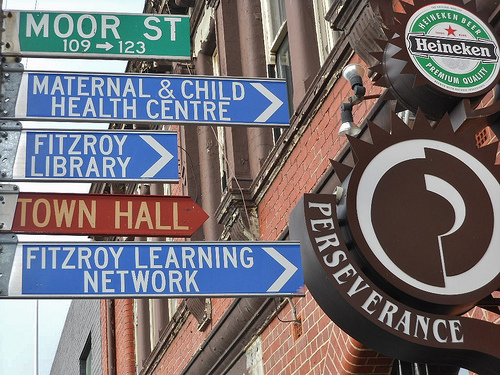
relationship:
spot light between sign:
[327, 59, 379, 134] [292, 106, 496, 356]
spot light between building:
[327, 59, 379, 134] [46, 1, 495, 373]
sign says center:
[0, 69, 292, 128] [29, 28, 424, 330]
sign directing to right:
[0, 69, 292, 128] [206, 17, 468, 368]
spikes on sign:
[303, 106, 499, 167] [303, 106, 498, 370]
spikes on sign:
[368, 0, 426, 94] [367, 1, 499, 105]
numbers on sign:
[61, 38, 144, 55] [2, 5, 192, 60]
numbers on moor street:
[61, 38, 144, 55] [25, 10, 182, 40]